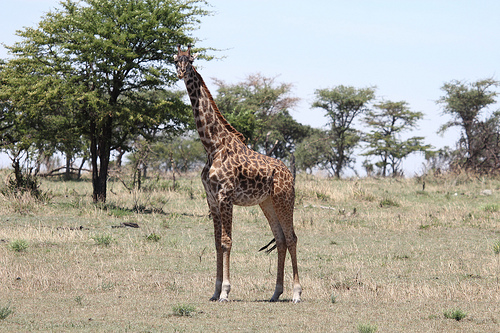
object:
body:
[198, 148, 304, 304]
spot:
[188, 89, 199, 98]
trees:
[0, 0, 231, 208]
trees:
[306, 84, 378, 179]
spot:
[220, 148, 229, 164]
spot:
[190, 81, 199, 90]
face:
[170, 54, 194, 79]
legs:
[210, 209, 222, 294]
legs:
[216, 204, 232, 298]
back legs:
[274, 196, 304, 294]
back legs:
[257, 203, 288, 293]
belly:
[230, 183, 273, 208]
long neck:
[179, 70, 245, 151]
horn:
[185, 41, 193, 54]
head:
[171, 48, 194, 80]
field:
[0, 166, 498, 332]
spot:
[190, 97, 197, 107]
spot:
[209, 125, 217, 140]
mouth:
[177, 71, 191, 80]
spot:
[208, 173, 217, 182]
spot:
[209, 123, 219, 135]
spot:
[240, 167, 249, 177]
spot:
[269, 165, 278, 175]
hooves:
[289, 291, 306, 304]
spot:
[202, 124, 212, 141]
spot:
[203, 112, 211, 125]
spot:
[248, 157, 260, 171]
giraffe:
[168, 47, 305, 304]